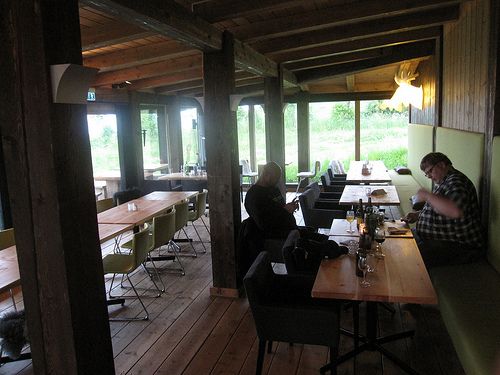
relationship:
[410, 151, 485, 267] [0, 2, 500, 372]
man in eating area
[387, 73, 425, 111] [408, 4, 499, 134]
light on wall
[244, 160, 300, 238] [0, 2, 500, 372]
man in eating area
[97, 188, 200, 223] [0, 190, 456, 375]
table on patio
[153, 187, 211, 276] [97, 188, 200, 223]
chairs by table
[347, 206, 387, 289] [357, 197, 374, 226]
glasses for wine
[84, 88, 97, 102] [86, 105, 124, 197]
sign at exit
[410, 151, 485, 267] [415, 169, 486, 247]
man wearing checkered shirt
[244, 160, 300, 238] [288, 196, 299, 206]
man looking at phone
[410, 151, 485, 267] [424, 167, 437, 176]
man wearing glasses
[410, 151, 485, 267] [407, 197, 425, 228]
man pouring drink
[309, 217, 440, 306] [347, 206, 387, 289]
table holding drinks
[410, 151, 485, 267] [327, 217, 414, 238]
man sitting at table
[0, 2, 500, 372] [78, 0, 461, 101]
room has rafters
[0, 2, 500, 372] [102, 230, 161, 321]
room has empty chair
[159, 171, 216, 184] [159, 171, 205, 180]
table made of wood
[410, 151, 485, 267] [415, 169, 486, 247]
man wearing plaid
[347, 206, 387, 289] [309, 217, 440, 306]
glasses on table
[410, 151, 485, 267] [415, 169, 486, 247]
man wearing flannel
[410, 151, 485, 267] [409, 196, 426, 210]
man pouring syrup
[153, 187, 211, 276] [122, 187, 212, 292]
chairs in a row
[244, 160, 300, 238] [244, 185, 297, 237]
man wearing black shirt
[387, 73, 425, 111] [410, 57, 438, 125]
light on paneling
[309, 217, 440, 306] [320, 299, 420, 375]
table has legs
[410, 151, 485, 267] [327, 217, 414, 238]
man at table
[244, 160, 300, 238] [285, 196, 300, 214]
man reading menu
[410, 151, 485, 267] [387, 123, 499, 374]
man sits at booth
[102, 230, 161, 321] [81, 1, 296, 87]
room has beams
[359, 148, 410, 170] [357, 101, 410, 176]
grass outside of window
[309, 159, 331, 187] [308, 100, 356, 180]
grass outside of window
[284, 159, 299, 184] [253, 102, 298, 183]
grass outside of window